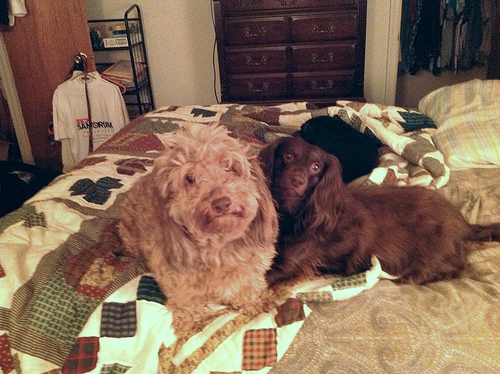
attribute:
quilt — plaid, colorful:
[300, 86, 446, 180]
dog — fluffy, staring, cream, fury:
[8, 91, 299, 373]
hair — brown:
[311, 160, 443, 255]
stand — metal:
[46, 14, 169, 131]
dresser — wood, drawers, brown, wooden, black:
[206, 6, 385, 111]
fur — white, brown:
[190, 247, 284, 319]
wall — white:
[141, 7, 225, 113]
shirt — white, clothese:
[44, 57, 132, 175]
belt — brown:
[56, 49, 106, 164]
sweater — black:
[293, 106, 373, 176]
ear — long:
[289, 140, 377, 240]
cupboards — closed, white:
[85, 16, 146, 49]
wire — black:
[111, 7, 157, 102]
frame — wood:
[5, 5, 110, 157]